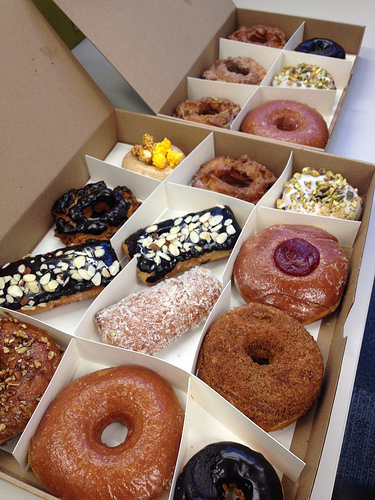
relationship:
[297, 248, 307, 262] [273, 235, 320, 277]
part of jam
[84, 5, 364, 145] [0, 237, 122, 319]
box assorted donuts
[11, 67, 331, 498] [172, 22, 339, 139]
box assorted donuts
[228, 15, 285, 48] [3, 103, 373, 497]
donut in box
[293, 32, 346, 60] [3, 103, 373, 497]
donut in box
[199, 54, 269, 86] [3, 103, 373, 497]
donut in box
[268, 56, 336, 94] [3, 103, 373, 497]
donut in box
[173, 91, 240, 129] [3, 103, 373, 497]
donut in box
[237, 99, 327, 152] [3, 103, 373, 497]
donut in box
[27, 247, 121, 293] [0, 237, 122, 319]
nuts are on donuts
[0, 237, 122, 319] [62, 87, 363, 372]
donuts in a box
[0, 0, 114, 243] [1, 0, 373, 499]
cover of box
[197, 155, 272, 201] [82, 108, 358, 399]
donut in box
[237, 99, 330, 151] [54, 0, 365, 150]
donut in box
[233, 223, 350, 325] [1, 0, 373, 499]
donut in box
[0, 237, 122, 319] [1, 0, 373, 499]
donuts in box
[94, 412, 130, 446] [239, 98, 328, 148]
hole in donut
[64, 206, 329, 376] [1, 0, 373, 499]
donuts in box